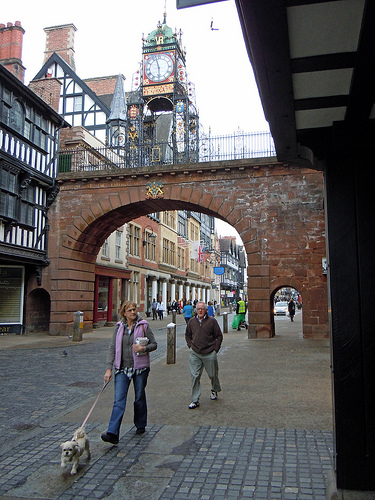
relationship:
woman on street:
[93, 296, 163, 458] [27, 334, 141, 474]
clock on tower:
[138, 50, 178, 96] [129, 4, 204, 145]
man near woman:
[170, 300, 243, 416] [93, 296, 163, 458]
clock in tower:
[138, 50, 178, 96] [129, 4, 204, 145]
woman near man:
[93, 296, 163, 458] [170, 300, 243, 416]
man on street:
[170, 300, 243, 416] [27, 334, 141, 474]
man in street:
[170, 300, 243, 416] [27, 334, 141, 474]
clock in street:
[138, 50, 178, 96] [27, 334, 141, 474]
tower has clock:
[129, 4, 204, 145] [138, 50, 178, 96]